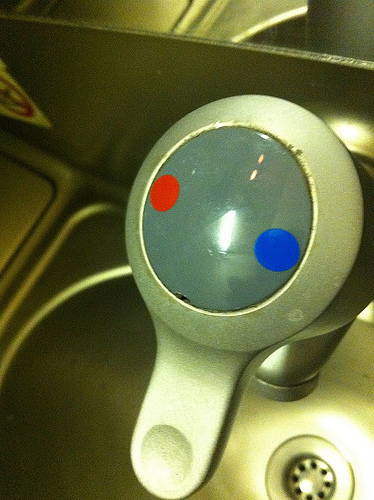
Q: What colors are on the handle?
A: Red and blue.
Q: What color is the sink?
A: Steel.